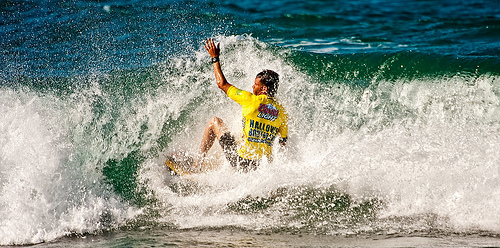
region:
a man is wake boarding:
[167, 37, 285, 177]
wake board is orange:
[162, 156, 222, 176]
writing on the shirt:
[247, 118, 277, 145]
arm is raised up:
[205, 36, 244, 103]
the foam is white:
[2, 29, 499, 243]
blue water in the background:
[1, 1, 495, 71]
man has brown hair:
[257, 68, 277, 93]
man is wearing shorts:
[220, 132, 258, 171]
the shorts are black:
[217, 130, 262, 174]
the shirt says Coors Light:
[255, 103, 278, 122]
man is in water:
[205, 58, 285, 175]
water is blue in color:
[370, 12, 437, 37]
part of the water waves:
[368, 139, 466, 207]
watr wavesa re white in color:
[413, 141, 482, 211]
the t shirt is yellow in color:
[233, 84, 275, 156]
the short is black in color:
[209, 124, 254, 176]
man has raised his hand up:
[221, 52, 285, 137]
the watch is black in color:
[200, 50, 232, 67]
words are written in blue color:
[253, 116, 286, 146]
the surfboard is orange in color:
[156, 151, 232, 178]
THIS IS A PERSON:
[184, 61, 301, 178]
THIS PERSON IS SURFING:
[187, 37, 298, 171]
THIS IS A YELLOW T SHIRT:
[247, 114, 282, 128]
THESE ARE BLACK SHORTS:
[221, 138, 236, 155]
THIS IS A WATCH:
[207, 57, 220, 62]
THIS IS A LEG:
[175, 125, 222, 178]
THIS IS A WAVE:
[361, 95, 435, 150]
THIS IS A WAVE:
[33, 95, 84, 175]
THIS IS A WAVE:
[313, 81, 441, 167]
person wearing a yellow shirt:
[157, 34, 297, 175]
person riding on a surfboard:
[149, 32, 299, 192]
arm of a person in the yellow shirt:
[198, 31, 248, 107]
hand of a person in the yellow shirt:
[200, 34, 223, 64]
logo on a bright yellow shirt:
[254, 99, 279, 126]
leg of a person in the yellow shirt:
[181, 114, 243, 174]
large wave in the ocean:
[0, 33, 496, 247]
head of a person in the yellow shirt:
[252, 69, 282, 99]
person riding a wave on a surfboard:
[151, 19, 298, 186]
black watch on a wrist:
[207, 52, 224, 68]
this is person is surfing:
[217, 70, 300, 150]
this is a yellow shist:
[246, 105, 288, 144]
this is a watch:
[204, 47, 222, 71]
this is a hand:
[204, 34, 226, 96]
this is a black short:
[221, 134, 228, 141]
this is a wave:
[424, 124, 456, 166]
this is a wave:
[395, 87, 477, 139]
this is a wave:
[357, 48, 449, 78]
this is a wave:
[64, 79, 159, 144]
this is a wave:
[59, 60, 173, 110]